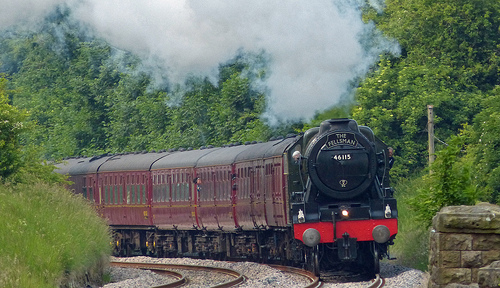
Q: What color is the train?
A: Red and black.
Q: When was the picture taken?
A: Daytime.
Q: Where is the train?
A: On the tracks.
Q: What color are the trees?
A: Green.